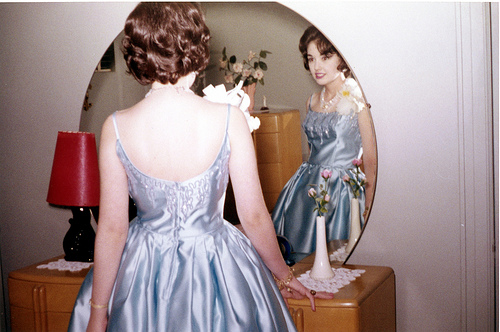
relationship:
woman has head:
[85, 0, 319, 331] [124, 2, 211, 96]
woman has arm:
[85, 0, 319, 331] [225, 108, 317, 309]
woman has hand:
[85, 0, 319, 331] [276, 263, 317, 311]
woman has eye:
[85, 0, 319, 331] [321, 56, 332, 63]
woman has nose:
[85, 0, 319, 331] [313, 59, 321, 70]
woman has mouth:
[85, 0, 319, 331] [314, 72, 327, 78]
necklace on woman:
[319, 78, 354, 105] [85, 0, 319, 331]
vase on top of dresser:
[309, 216, 337, 281] [5, 253, 394, 330]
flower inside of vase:
[253, 70, 265, 81] [309, 216, 337, 281]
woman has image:
[85, 0, 319, 331] [268, 25, 368, 244]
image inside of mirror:
[268, 25, 368, 244] [79, 0, 379, 268]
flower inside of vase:
[322, 168, 332, 184] [309, 216, 337, 281]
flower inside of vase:
[307, 187, 319, 199] [309, 216, 337, 281]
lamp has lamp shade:
[48, 132, 101, 261] [48, 130, 102, 207]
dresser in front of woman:
[5, 253, 394, 330] [85, 0, 319, 331]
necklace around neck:
[319, 78, 354, 105] [321, 73, 350, 99]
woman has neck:
[85, 0, 319, 331] [321, 73, 350, 99]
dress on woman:
[71, 112, 294, 331] [85, 0, 319, 331]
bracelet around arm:
[280, 268, 299, 289] [225, 108, 317, 309]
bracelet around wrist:
[280, 268, 299, 289] [276, 265, 299, 290]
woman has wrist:
[85, 0, 319, 331] [276, 265, 299, 290]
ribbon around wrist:
[86, 303, 112, 311] [89, 300, 113, 315]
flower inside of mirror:
[322, 168, 332, 184] [79, 0, 379, 268]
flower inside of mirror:
[307, 187, 319, 199] [79, 0, 379, 268]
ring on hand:
[310, 289, 318, 299] [276, 263, 317, 311]